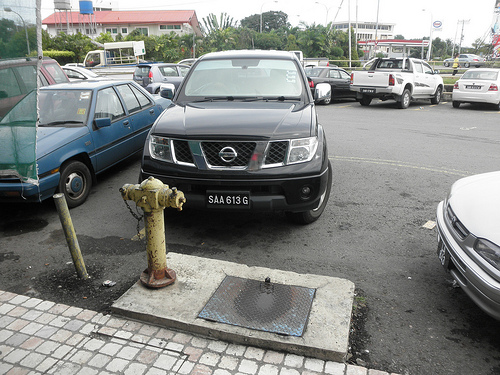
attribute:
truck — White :
[346, 52, 445, 107]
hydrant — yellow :
[120, 175, 187, 289]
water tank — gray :
[48, 0, 73, 46]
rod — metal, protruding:
[51, 192, 91, 282]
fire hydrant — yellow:
[116, 174, 187, 289]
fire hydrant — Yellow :
[114, 172, 195, 292]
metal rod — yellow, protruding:
[48, 188, 92, 273]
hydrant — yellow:
[106, 169, 176, 286]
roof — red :
[42, 9, 199, 26]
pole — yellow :
[52, 191, 90, 281]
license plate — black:
[199, 186, 265, 214]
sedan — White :
[448, 65, 498, 110]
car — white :
[164, 57, 341, 219]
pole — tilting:
[117, 136, 224, 277]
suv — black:
[141, 32, 338, 224]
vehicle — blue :
[0, 69, 167, 216]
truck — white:
[350, 56, 445, 106]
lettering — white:
[206, 193, 249, 205]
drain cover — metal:
[192, 269, 322, 341]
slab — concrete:
[103, 244, 361, 360]